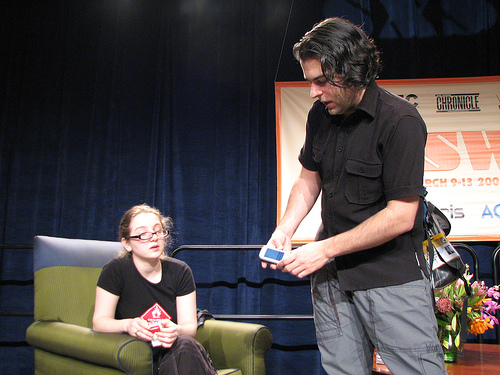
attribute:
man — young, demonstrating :
[252, 6, 451, 374]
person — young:
[110, 200, 217, 374]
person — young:
[273, 10, 440, 373]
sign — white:
[262, 74, 497, 254]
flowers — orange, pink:
[433, 257, 499, 339]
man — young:
[298, 35, 413, 321]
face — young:
[285, 28, 377, 94]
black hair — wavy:
[291, 9, 372, 74]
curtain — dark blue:
[100, 37, 298, 217]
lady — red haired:
[81, 198, 207, 371]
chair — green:
[20, 225, 277, 373]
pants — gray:
[301, 268, 438, 373]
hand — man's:
[255, 234, 334, 281]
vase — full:
[433, 261, 495, 367]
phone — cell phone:
[260, 238, 292, 264]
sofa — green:
[41, 267, 115, 359]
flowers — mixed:
[423, 269, 498, 349]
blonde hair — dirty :
[96, 192, 186, 261]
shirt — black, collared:
[295, 78, 425, 288]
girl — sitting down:
[91, 200, 218, 372]